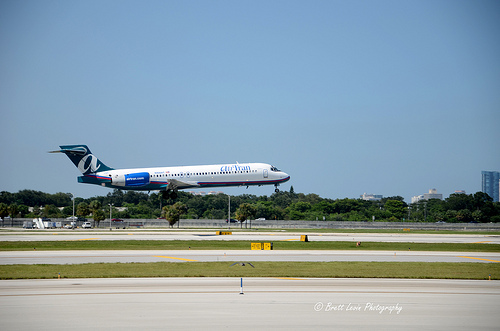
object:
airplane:
[48, 144, 290, 196]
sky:
[11, 6, 490, 190]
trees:
[474, 191, 500, 224]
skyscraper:
[481, 170, 499, 202]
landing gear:
[162, 188, 178, 200]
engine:
[111, 172, 151, 188]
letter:
[77, 154, 101, 174]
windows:
[247, 171, 249, 173]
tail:
[48, 144, 116, 190]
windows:
[487, 175, 490, 177]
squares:
[250, 242, 262, 250]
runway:
[7, 221, 496, 265]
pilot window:
[270, 167, 273, 171]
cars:
[55, 221, 62, 229]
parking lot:
[0, 214, 145, 228]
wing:
[167, 178, 200, 187]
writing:
[220, 166, 224, 172]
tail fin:
[48, 149, 85, 154]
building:
[412, 187, 444, 208]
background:
[287, 166, 493, 204]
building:
[360, 190, 383, 201]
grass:
[3, 262, 499, 283]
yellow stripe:
[151, 255, 199, 262]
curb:
[0, 277, 494, 294]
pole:
[72, 192, 74, 230]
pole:
[110, 205, 112, 230]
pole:
[228, 195, 231, 227]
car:
[81, 221, 91, 228]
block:
[299, 235, 308, 242]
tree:
[233, 203, 250, 228]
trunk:
[241, 222, 243, 228]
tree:
[172, 201, 186, 228]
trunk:
[171, 225, 173, 228]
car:
[43, 220, 54, 229]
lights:
[70, 197, 76, 201]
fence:
[0, 218, 233, 230]